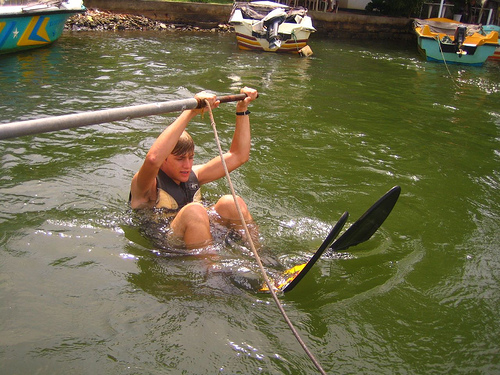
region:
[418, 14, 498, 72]
blue boat in water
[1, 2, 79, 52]
blue and yellow boat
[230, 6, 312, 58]
white and yellow boat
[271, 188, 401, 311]
black water skis in water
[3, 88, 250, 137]
grey metal jet ski pole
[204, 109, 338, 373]
brown rope attached to pole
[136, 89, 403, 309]
man holding jet ski pole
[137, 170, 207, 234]
black and tan life vest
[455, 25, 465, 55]
black motor on boat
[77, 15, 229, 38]
rocks next to water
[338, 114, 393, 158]
ripple in the water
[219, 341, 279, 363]
ripple in the water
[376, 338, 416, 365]
ripple in the water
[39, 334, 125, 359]
ripple in the water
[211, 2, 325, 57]
boat parked at dock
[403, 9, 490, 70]
boat parked at dock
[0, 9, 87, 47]
boat at the dock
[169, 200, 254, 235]
knees of the boy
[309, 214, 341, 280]
ski on the boy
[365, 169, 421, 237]
ski on the boy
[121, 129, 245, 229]
young male holding onto gray pole in green water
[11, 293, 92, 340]
green and white water in river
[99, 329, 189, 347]
green and white water in river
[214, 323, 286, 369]
green and white water in river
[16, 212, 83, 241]
green and white water in river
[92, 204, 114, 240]
green and white water in river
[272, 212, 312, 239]
green and white water in river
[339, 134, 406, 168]
fish swimming in green river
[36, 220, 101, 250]
fish swimming in green river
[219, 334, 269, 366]
fish swimming in green river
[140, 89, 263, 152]
boy is holding on to the pole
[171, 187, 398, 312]
man is on water skis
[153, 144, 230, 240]
man is wearing a life vest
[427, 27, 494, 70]
boat is aqua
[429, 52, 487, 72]
blue stripe on bottom of boat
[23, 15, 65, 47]
yellow and blue design on the boat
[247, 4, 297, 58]
boat motor is out of the water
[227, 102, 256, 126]
man has a watch on his left arm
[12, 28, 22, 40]
white star on the boat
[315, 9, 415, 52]
wall along the water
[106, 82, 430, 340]
a boy holding on to a pole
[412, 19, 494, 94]
a blue boat with yellow on top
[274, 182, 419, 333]
black water skis with yellow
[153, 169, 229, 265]
black and yellow water vest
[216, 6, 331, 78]
a white boat with brown trim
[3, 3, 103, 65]
a blue and yellow boat on the left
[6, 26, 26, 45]
a small white star on boat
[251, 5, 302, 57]
a white and black motor out of water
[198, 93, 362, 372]
a rope coming from the pole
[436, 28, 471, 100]
a rope coming off the blue boat